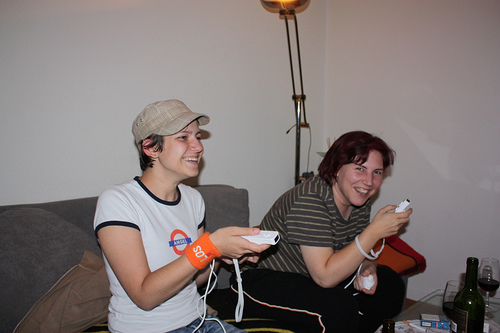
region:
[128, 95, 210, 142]
tan cap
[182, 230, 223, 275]
orange and white wrist band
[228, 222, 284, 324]
white video game control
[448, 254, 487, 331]
dark green bottle on coffee table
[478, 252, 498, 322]
wine glass with red wine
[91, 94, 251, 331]
girl in white shirt playing video game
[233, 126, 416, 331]
girl in stripped shirt smiling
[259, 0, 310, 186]
metal floor lamp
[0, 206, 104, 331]
grey sofa cushion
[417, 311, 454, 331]
pack of cigarettes sitting on coffee table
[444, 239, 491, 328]
the bottle is dark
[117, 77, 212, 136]
the girl wears a cap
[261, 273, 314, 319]
the pants are black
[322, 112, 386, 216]
the girl is smiling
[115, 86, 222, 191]
the girl is happy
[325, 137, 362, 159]
the girl has hair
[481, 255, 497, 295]
the glass is half full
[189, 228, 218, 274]
the wristband is orange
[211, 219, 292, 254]
the controller is white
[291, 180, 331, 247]
the shirt is striped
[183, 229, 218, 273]
an orange wrist band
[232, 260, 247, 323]
string of the controller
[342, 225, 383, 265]
string on the wrist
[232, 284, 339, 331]
line on the pants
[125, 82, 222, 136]
the tan hat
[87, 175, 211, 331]
a white tee shirt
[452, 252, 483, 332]
a bottle of wine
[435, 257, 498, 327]
glasses on the table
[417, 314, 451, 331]
a box of cigarettes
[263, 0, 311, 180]
a floor lamp in the corner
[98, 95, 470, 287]
two girls playing a Wii game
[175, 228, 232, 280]
an orange wrist band on the girl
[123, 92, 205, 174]
a light brown cap on the girl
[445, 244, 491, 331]
the top of a beer bottle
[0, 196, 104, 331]
a brown couch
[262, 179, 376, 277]
a girl wearing a brown and white striped shirt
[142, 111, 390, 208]
two girls smiling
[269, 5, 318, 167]
a tall lamp in the corner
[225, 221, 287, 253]
a Wii controller in a hand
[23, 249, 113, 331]
a brown blanket on the couch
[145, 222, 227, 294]
orange and white wrist guard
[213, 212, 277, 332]
a wii remote and strap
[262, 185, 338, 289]
a gray and white shirt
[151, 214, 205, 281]
rde white and blue logo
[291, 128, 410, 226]
woman smiling at camera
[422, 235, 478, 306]
bottle of wine on table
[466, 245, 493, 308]
glass of wine on table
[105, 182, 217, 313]
a white shirt with black neck and arm lining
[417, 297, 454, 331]
pack of cigarettes on table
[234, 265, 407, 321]
black shirt with white stripe